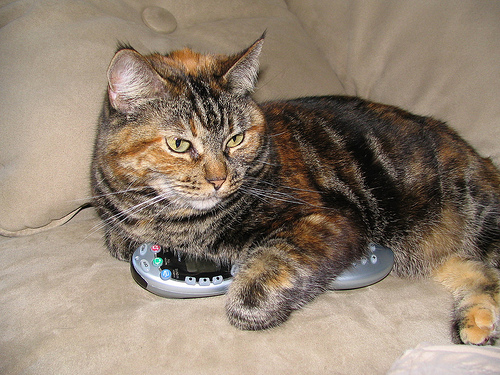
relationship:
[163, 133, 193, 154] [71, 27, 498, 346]
eye on cat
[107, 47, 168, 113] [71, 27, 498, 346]
ear on cat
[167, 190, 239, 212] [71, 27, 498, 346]
mouth on cat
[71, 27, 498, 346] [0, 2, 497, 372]
cat on couch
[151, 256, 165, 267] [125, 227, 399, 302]
button on remote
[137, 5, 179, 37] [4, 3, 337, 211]
button in middle of pillow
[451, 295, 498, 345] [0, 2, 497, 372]
paw on couch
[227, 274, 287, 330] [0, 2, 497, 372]
paw on couch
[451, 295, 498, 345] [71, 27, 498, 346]
paw on cat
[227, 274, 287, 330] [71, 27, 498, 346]
paw on cat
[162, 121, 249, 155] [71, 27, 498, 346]
eyes on cat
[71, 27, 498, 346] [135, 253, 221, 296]
cat holding remote control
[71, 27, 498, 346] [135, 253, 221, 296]
cat sitting on remote control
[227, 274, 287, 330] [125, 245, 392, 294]
paw wrapped around remotecontrol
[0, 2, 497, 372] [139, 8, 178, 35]
couch covered by button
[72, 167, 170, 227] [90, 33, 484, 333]
whiskers on cat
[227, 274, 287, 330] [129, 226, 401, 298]
paw on remote control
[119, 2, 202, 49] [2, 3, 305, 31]
button on pillow